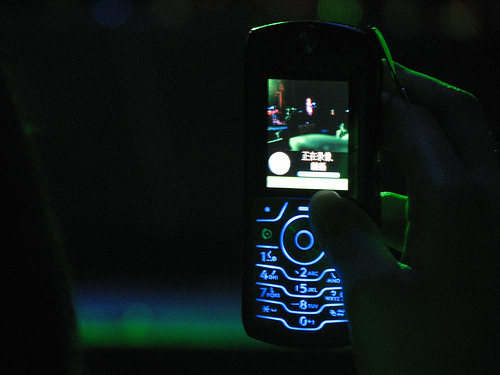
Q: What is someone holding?
A: A cellphone.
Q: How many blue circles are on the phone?
A: Two.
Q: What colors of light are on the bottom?
A: Blue and Green.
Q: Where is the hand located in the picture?
A: On the right side.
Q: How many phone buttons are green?
A: One.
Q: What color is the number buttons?
A: Blue.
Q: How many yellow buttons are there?
A: None.